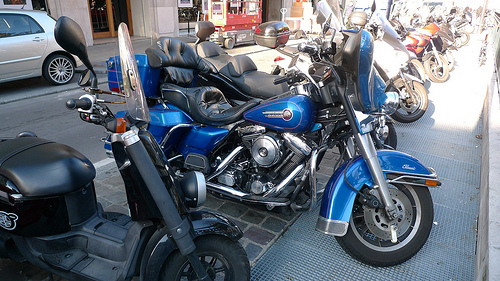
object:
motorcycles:
[1, 16, 248, 281]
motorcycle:
[102, 28, 442, 269]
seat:
[0, 137, 97, 203]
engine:
[246, 130, 318, 181]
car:
[0, 6, 83, 86]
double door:
[88, 0, 134, 39]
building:
[0, 0, 178, 48]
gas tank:
[243, 93, 313, 133]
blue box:
[106, 53, 159, 98]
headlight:
[382, 91, 399, 115]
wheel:
[332, 172, 443, 267]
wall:
[470, 16, 500, 281]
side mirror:
[54, 16, 88, 60]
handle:
[64, 97, 92, 111]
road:
[1, 29, 500, 281]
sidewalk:
[90, 23, 487, 281]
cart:
[196, 0, 263, 50]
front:
[315, 18, 439, 268]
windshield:
[118, 22, 150, 124]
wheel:
[41, 54, 74, 85]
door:
[0, 14, 49, 80]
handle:
[32, 37, 44, 41]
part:
[249, 131, 281, 166]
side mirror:
[321, 13, 334, 34]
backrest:
[145, 35, 214, 87]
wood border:
[105, 0, 116, 37]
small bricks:
[260, 217, 288, 232]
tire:
[162, 238, 251, 281]